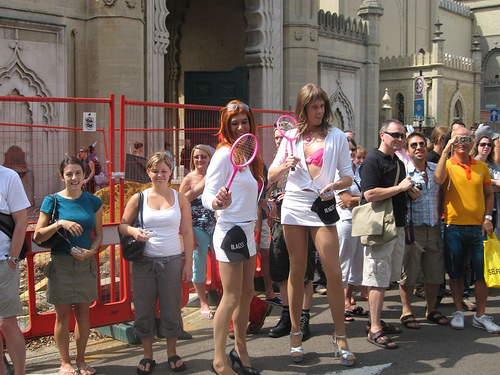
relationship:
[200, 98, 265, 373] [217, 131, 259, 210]
person holding racket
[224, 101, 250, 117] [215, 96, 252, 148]
sunglasses on head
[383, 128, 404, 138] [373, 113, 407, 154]
sunglasses on head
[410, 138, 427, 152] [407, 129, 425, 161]
sunglasses on head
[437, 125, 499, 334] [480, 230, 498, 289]
man holds bag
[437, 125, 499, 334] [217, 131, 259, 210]
man wears racket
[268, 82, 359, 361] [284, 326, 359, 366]
person wears shoes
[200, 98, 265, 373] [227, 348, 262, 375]
person wears heels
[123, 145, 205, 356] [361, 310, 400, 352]
person wears shoes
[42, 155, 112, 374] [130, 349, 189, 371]
person wears shoes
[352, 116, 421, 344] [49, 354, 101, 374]
person wears shoes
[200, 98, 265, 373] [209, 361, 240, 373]
person wears heels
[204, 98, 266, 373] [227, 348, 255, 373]
person wears heels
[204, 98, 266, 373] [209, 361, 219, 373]
person wears heels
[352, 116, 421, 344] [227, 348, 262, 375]
person wears heels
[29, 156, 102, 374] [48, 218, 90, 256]
person has camera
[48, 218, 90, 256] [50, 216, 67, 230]
camera around wrist